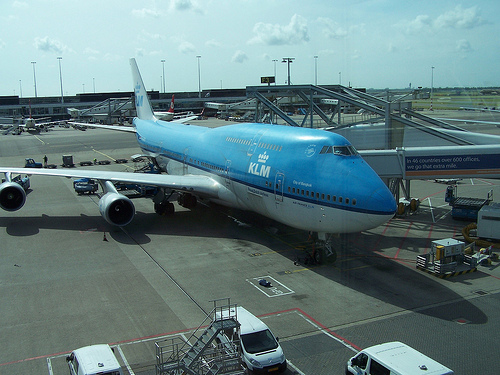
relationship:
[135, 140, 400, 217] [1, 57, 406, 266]
stripe on plane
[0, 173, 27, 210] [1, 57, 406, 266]
engine on plane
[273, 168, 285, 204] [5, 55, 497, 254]
door on plane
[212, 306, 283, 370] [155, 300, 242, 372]
van near staircase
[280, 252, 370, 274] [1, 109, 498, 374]
line on tarmac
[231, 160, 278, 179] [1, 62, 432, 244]
klm on plane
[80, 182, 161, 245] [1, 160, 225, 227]
engine on wing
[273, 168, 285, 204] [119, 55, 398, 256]
door on airplane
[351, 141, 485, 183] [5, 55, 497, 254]
jetbridge near plane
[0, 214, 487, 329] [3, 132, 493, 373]
shadow on tarmac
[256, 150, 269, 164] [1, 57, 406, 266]
crown on plane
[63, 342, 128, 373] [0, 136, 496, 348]
van on tarmac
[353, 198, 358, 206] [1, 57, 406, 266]
window on plane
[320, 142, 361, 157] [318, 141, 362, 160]
windows on cockpit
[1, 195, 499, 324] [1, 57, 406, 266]
shadow of plane